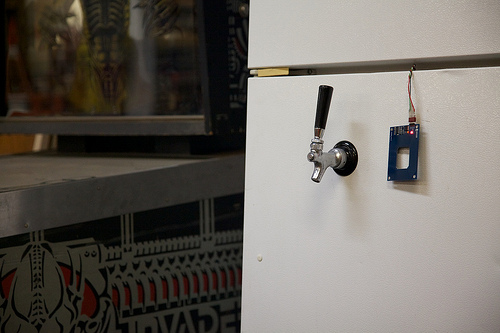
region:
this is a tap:
[307, 83, 359, 183]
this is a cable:
[385, 72, 422, 184]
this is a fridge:
[242, 3, 490, 318]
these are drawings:
[3, 244, 233, 331]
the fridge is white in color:
[256, 202, 391, 331]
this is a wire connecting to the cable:
[404, 68, 419, 125]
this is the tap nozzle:
[306, 168, 330, 185]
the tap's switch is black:
[311, 84, 336, 134]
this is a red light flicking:
[405, 129, 418, 139]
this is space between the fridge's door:
[250, 64, 498, 79]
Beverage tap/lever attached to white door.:
[303, 81, 363, 197]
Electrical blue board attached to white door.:
[380, 120, 425, 190]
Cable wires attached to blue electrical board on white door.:
[400, 66, 420, 121]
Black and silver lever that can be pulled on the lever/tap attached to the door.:
[305, 80, 335, 150]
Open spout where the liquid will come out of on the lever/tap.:
[305, 161, 325, 181]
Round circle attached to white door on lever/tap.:
[332, 135, 357, 175]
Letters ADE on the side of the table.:
[167, 295, 239, 330]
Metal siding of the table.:
[0, 160, 240, 231]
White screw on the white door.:
[250, 251, 265, 266]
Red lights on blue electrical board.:
[390, 123, 420, 134]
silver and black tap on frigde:
[297, 85, 359, 185]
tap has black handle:
[312, 80, 334, 131]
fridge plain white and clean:
[236, 2, 498, 329]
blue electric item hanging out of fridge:
[385, 123, 420, 183]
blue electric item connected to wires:
[385, 62, 422, 182]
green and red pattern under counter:
[1, 190, 248, 331]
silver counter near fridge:
[2, 132, 247, 240]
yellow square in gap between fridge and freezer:
[252, 67, 293, 78]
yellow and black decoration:
[72, 0, 138, 112]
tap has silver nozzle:
[306, 143, 338, 183]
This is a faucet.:
[287, 84, 366, 183]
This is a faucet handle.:
[305, 78, 337, 140]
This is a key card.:
[375, 114, 437, 189]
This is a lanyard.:
[391, 61, 426, 119]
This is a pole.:
[250, 44, 494, 90]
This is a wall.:
[228, 24, 498, 324]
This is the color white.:
[299, 243, 398, 319]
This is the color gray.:
[320, 154, 330, 166]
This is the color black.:
[323, 96, 327, 112]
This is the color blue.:
[394, 128, 409, 142]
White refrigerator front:
[243, 0, 499, 331]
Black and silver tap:
[302, 83, 362, 198]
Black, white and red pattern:
[10, 239, 230, 326]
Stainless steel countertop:
[5, 141, 242, 208]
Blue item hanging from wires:
[372, 66, 429, 188]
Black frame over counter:
[5, 3, 227, 138]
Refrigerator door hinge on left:
[245, 56, 295, 88]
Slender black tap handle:
[303, 79, 339, 139]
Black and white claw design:
[57, 250, 92, 307]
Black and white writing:
[123, 305, 234, 331]